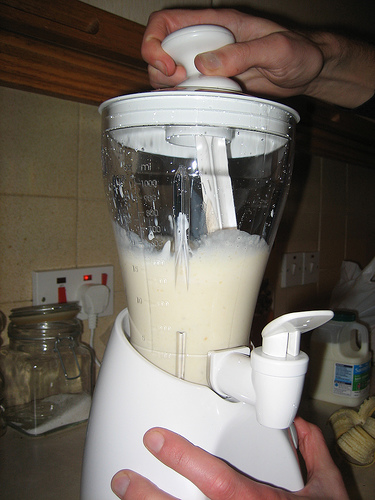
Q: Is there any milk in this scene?
A: Yes, there is milk.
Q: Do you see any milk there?
A: Yes, there is milk.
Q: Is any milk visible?
A: Yes, there is milk.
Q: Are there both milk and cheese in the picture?
A: No, there is milk but no cheese.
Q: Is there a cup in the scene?
A: No, there are no cups.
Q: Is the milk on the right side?
A: Yes, the milk is on the right of the image.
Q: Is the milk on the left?
A: No, the milk is on the right of the image.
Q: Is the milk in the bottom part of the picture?
A: Yes, the milk is in the bottom of the image.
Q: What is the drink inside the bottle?
A: The drink is milk.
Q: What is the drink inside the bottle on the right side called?
A: The drink is milk.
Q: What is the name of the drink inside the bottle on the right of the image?
A: The drink is milk.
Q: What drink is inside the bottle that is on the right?
A: The drink is milk.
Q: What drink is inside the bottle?
A: The drink is milk.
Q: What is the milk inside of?
A: The milk is inside the bottle.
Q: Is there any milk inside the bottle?
A: Yes, there is milk inside the bottle.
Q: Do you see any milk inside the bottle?
A: Yes, there is milk inside the bottle.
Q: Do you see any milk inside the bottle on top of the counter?
A: Yes, there is milk inside the bottle.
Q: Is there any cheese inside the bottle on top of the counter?
A: No, there is milk inside the bottle.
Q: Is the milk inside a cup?
A: No, the milk is inside the bottle.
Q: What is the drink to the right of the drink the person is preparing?
A: The drink is milk.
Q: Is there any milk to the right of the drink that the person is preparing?
A: Yes, there is milk to the right of the drink.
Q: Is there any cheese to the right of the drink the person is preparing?
A: No, there is milk to the right of the drink.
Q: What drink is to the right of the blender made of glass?
A: The drink is milk.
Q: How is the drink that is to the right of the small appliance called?
A: The drink is milk.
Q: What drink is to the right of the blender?
A: The drink is milk.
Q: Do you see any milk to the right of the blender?
A: Yes, there is milk to the right of the blender.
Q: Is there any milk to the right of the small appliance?
A: Yes, there is milk to the right of the blender.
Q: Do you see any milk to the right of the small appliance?
A: Yes, there is milk to the right of the blender.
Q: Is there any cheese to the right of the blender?
A: No, there is milk to the right of the blender.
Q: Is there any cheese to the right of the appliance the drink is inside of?
A: No, there is milk to the right of the blender.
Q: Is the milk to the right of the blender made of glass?
A: Yes, the milk is to the right of the blender.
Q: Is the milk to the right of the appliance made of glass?
A: Yes, the milk is to the right of the blender.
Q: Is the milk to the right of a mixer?
A: No, the milk is to the right of the blender.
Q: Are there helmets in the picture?
A: No, there are no helmets.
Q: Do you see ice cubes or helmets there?
A: No, there are no helmets or ice cubes.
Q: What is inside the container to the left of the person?
A: The powder is inside the canister.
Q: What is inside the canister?
A: The powder is inside the canister.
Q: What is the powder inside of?
A: The powder is inside the canister.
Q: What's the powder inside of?
A: The powder is inside the canister.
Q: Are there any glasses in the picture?
A: No, there are no glasses.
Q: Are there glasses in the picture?
A: No, there are no glasses.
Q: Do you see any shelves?
A: No, there are no shelves.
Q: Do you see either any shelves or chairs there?
A: No, there are no shelves or chairs.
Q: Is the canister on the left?
A: Yes, the canister is on the left of the image.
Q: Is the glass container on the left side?
A: Yes, the canister is on the left of the image.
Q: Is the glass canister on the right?
A: No, the canister is on the left of the image.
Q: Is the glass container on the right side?
A: No, the canister is on the left of the image.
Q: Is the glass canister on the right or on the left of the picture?
A: The canister is on the left of the image.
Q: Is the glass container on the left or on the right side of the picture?
A: The canister is on the left of the image.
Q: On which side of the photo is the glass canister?
A: The canister is on the left of the image.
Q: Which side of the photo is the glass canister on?
A: The canister is on the left of the image.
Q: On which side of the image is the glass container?
A: The canister is on the left of the image.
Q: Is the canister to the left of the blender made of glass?
A: Yes, the canister is made of glass.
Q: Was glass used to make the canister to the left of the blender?
A: Yes, the canister is made of glass.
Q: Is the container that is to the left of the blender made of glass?
A: Yes, the canister is made of glass.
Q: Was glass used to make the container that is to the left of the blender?
A: Yes, the canister is made of glass.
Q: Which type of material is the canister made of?
A: The canister is made of glass.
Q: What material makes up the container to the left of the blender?
A: The canister is made of glass.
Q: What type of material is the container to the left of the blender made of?
A: The canister is made of glass.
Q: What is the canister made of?
A: The canister is made of glass.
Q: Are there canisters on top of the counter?
A: Yes, there is a canister on top of the counter.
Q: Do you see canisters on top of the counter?
A: Yes, there is a canister on top of the counter.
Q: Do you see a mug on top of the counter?
A: No, there is a canister on top of the counter.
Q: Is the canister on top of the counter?
A: Yes, the canister is on top of the counter.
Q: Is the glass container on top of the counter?
A: Yes, the canister is on top of the counter.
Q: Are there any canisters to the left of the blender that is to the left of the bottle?
A: Yes, there is a canister to the left of the blender.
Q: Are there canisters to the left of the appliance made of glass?
A: Yes, there is a canister to the left of the blender.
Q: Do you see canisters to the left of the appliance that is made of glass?
A: Yes, there is a canister to the left of the blender.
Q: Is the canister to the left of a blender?
A: Yes, the canister is to the left of a blender.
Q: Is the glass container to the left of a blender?
A: Yes, the canister is to the left of a blender.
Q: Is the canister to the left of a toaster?
A: No, the canister is to the left of a blender.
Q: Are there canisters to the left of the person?
A: Yes, there is a canister to the left of the person.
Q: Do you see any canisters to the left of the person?
A: Yes, there is a canister to the left of the person.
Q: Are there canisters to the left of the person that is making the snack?
A: Yes, there is a canister to the left of the person.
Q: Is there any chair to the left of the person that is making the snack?
A: No, there is a canister to the left of the person.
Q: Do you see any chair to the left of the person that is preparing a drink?
A: No, there is a canister to the left of the person.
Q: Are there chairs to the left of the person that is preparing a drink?
A: No, there is a canister to the left of the person.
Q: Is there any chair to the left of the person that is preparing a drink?
A: No, there is a canister to the left of the person.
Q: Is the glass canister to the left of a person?
A: Yes, the canister is to the left of a person.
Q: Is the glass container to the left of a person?
A: Yes, the canister is to the left of a person.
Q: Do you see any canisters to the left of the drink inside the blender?
A: Yes, there is a canister to the left of the drink.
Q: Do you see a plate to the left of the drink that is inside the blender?
A: No, there is a canister to the left of the drink.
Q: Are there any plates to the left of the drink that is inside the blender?
A: No, there is a canister to the left of the drink.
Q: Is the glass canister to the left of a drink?
A: Yes, the canister is to the left of a drink.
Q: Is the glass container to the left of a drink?
A: Yes, the canister is to the left of a drink.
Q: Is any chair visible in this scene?
A: No, there are no chairs.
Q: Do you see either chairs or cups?
A: No, there are no chairs or cups.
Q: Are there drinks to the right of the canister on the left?
A: Yes, there is a drink to the right of the canister.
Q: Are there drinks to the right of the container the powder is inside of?
A: Yes, there is a drink to the right of the canister.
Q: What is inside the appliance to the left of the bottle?
A: The drink is inside the blender.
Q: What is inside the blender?
A: The drink is inside the blender.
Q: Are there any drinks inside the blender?
A: Yes, there is a drink inside the blender.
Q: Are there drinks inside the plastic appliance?
A: Yes, there is a drink inside the blender.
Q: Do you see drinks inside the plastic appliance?
A: Yes, there is a drink inside the blender.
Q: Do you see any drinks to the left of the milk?
A: Yes, there is a drink to the left of the milk.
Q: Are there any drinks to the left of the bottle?
A: Yes, there is a drink to the left of the bottle.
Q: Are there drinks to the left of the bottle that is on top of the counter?
A: Yes, there is a drink to the left of the bottle.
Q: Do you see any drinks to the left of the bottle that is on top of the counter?
A: Yes, there is a drink to the left of the bottle.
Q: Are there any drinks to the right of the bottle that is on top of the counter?
A: No, the drink is to the left of the bottle.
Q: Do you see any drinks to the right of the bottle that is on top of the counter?
A: No, the drink is to the left of the bottle.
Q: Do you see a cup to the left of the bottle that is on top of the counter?
A: No, there is a drink to the left of the bottle.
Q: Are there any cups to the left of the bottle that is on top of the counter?
A: No, there is a drink to the left of the bottle.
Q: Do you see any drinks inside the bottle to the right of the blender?
A: Yes, there is a drink inside the bottle.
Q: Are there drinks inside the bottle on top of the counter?
A: Yes, there is a drink inside the bottle.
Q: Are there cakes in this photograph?
A: No, there are no cakes.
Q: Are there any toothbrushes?
A: No, there are no toothbrushes.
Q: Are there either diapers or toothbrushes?
A: No, there are no toothbrushes or diapers.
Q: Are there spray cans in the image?
A: No, there are no spray cans.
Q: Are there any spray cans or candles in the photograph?
A: No, there are no spray cans or candles.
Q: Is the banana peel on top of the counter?
A: Yes, the banana peel is on top of the counter.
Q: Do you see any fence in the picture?
A: No, there are no fences.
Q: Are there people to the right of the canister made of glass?
A: Yes, there is a person to the right of the canister.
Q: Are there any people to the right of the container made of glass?
A: Yes, there is a person to the right of the canister.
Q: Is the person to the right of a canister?
A: Yes, the person is to the right of a canister.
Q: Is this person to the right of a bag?
A: No, the person is to the right of a canister.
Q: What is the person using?
A: The person is using a blender.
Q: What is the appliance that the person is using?
A: The appliance is a blender.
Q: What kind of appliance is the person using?
A: The person is using a blender.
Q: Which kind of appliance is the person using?
A: The person is using a blender.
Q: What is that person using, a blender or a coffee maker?
A: The person is using a blender.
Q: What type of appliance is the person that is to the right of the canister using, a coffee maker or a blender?
A: The person is using a blender.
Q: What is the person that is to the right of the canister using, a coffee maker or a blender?
A: The person is using a blender.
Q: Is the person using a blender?
A: Yes, the person is using a blender.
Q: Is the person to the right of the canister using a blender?
A: Yes, the person is using a blender.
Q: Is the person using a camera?
A: No, the person is using a blender.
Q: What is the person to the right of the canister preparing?
A: The person is preparing a drink.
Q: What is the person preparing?
A: The person is preparing a drink.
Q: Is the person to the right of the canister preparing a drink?
A: Yes, the person is preparing a drink.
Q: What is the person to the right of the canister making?
A: The person is making the snack.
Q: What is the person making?
A: The person is making the snack.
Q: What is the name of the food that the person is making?
A: The food is a snack.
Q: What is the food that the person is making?
A: The food is a snack.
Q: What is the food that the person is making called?
A: The food is a snack.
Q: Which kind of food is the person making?
A: The person is making the snack.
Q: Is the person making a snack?
A: Yes, the person is making a snack.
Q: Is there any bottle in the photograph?
A: Yes, there is a bottle.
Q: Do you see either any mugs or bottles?
A: Yes, there is a bottle.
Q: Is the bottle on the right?
A: Yes, the bottle is on the right of the image.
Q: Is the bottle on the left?
A: No, the bottle is on the right of the image.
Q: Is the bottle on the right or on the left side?
A: The bottle is on the right of the image.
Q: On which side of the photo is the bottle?
A: The bottle is on the right of the image.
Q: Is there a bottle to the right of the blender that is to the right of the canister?
A: Yes, there is a bottle to the right of the blender.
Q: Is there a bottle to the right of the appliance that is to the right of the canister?
A: Yes, there is a bottle to the right of the blender.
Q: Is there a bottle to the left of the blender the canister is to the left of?
A: No, the bottle is to the right of the blender.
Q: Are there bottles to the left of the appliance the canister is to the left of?
A: No, the bottle is to the right of the blender.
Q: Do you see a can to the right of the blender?
A: No, there is a bottle to the right of the blender.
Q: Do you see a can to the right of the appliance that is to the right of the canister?
A: No, there is a bottle to the right of the blender.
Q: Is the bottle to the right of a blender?
A: Yes, the bottle is to the right of a blender.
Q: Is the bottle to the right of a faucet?
A: No, the bottle is to the right of a blender.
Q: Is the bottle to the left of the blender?
A: No, the bottle is to the right of the blender.